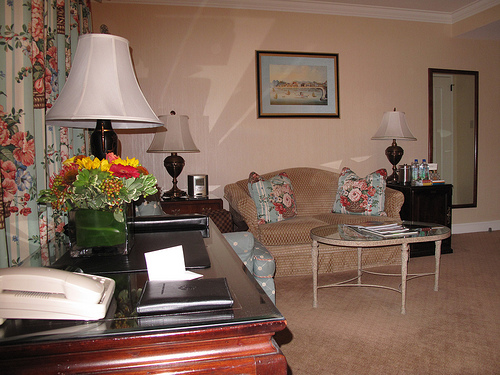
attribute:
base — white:
[7, 260, 119, 328]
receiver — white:
[4, 261, 105, 308]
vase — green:
[72, 209, 127, 246]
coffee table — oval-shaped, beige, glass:
[302, 218, 449, 311]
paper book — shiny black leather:
[139, 278, 232, 315]